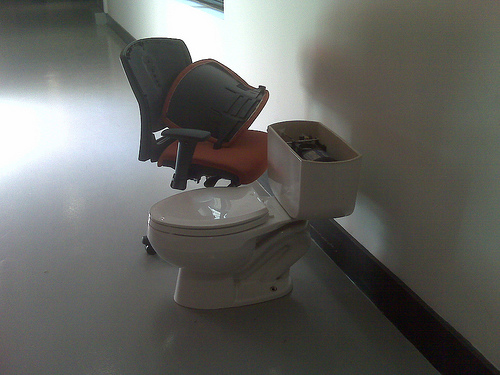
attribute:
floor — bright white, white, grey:
[3, 5, 448, 370]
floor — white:
[304, 263, 465, 320]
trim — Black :
[103, 12, 499, 372]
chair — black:
[111, 40, 194, 162]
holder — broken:
[262, 117, 363, 221]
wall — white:
[382, 39, 463, 178]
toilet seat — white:
[141, 181, 298, 312]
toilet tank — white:
[261, 114, 363, 229]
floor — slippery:
[44, 150, 84, 229]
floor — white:
[258, 290, 314, 332]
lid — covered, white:
[148, 179, 267, 231]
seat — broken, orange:
[120, 32, 270, 187]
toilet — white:
[134, 116, 364, 315]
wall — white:
[394, 152, 486, 289]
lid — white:
[148, 192, 267, 226]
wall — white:
[106, 0, 493, 370]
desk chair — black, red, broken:
[115, 35, 266, 187]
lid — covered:
[140, 176, 270, 242]